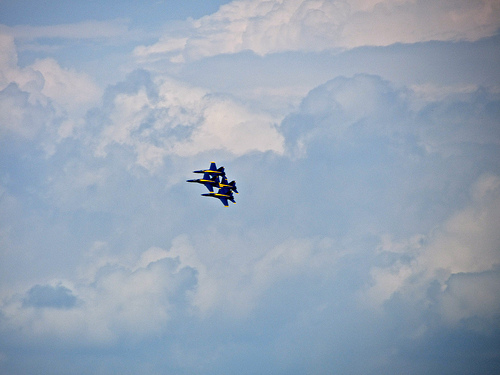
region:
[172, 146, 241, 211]
planes flying in unison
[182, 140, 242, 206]
planes are blue and yellow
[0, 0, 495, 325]
planes flying in clouds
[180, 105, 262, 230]
planes are leaning sideways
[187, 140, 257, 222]
planes have 1 wing on each side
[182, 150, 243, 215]
each plane has a tail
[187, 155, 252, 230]
middle of planes are yellow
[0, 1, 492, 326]
the clouds are covering whole sky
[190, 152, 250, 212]
planes are flying towards left of picture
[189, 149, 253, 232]
plane's tails are black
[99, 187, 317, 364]
the sky is white and blue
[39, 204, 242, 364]
the sky is white and blue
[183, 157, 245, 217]
four jets in tight formation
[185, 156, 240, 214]
four fighters in formation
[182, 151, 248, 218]
four planes in formation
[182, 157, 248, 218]
Blue Angels in formation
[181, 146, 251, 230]
thunderbirds flying in formation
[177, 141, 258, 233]
planes about to divide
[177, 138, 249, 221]
planes flying toward the left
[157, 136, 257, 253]
planes aloft in a cloudy sky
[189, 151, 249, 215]
Patriots jet team in formation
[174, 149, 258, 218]
four jets flying together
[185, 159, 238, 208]
four airplanes flying in formation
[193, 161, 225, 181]
airplane above airplane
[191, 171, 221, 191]
airplane in front of airplane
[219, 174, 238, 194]
airplane behind airplane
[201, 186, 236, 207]
airplane under airplane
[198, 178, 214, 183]
yellow stripe on fuselage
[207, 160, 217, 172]
blue airplane wing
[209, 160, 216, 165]
tip of wing is yellow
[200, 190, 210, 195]
nose of airplane is blue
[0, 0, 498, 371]
blue sky behind flying airplanes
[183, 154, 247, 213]
Four airplanes in the sky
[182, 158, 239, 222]
Four blue and yellow airplanes in the sky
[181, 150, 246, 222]
Blue and yellow airplanes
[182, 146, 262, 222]
Airplanes flying in the sky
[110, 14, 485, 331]
Fluffy clouds in the distance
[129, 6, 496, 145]
Fluffy clouds in the sky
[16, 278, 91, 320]
Dark cloud in the sky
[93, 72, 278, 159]
Dark and light clouds in the sky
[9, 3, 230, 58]
Blue sky with clouds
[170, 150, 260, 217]
Planes flying close together